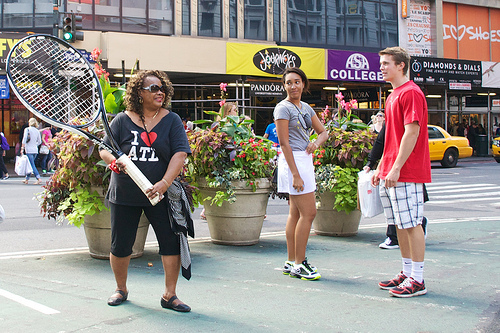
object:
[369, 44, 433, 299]
man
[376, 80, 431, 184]
shirt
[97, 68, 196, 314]
woman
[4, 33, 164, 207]
racket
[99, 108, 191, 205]
i <3 atl shirt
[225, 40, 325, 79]
journeys banner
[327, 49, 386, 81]
asa college banner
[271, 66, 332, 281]
woman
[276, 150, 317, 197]
skirt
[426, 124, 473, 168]
cab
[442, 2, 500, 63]
i <3 shoes banner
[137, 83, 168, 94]
sunglasses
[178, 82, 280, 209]
pot of flowers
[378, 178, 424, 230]
shorts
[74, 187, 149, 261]
flower pot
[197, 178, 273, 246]
flower pot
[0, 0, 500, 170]
building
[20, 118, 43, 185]
person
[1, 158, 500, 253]
street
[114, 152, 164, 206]
handle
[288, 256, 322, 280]
shoe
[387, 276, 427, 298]
shoe